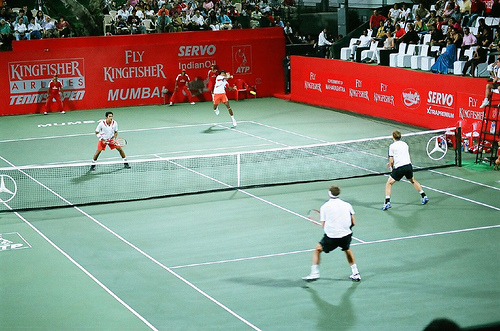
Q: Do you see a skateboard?
A: No, there are no skateboards.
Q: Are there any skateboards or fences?
A: No, there are no skateboards or fences.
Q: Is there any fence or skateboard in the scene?
A: No, there are no skateboards or fences.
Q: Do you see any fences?
A: No, there are no fences.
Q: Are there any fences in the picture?
A: No, there are no fences.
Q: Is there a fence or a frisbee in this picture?
A: No, there are no fences or frisbees.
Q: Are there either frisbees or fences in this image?
A: No, there are no fences or frisbees.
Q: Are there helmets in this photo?
A: No, there are no helmets.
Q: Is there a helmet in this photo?
A: No, there are no helmets.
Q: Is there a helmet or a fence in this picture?
A: No, there are no helmets or fences.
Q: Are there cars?
A: No, there are no cars.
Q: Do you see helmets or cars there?
A: No, there are no cars or helmets.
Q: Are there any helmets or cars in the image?
A: No, there are no cars or helmets.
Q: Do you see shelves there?
A: No, there are no shelves.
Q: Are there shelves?
A: No, there are no shelves.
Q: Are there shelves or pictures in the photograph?
A: No, there are no shelves or pictures.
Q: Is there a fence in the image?
A: No, there are no fences.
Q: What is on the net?
A: The logo is on the net.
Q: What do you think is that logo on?
A: The logo is on the net.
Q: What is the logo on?
A: The logo is on the net.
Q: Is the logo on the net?
A: Yes, the logo is on the net.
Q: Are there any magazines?
A: No, there are no magazines.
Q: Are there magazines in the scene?
A: No, there are no magazines.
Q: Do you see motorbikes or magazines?
A: No, there are no magazines or motorbikes.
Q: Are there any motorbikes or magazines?
A: No, there are no magazines or motorbikes.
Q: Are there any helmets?
A: No, there are no helmets.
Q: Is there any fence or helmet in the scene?
A: No, there are no helmets or fences.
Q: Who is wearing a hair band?
A: The man is wearing a hair band.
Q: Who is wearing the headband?
A: The man is wearing a hair band.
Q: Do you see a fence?
A: No, there are no fences.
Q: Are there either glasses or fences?
A: No, there are no fences or glasses.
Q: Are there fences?
A: No, there are no fences.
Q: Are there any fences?
A: No, there are no fences.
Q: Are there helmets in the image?
A: No, there are no helmets.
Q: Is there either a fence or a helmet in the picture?
A: No, there are no helmets or fences.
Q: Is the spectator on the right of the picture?
A: Yes, the spectator is on the right of the image.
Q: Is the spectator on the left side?
A: No, the spectator is on the right of the image.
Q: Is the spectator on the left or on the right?
A: The spectator is on the right of the image.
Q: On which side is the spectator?
A: The spectator is on the right of the image.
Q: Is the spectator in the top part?
A: Yes, the spectator is in the top of the image.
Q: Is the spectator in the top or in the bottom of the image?
A: The spectator is in the top of the image.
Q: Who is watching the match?
A: The spectator is watching the match.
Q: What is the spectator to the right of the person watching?
A: The spectator is watching the match.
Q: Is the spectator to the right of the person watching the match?
A: Yes, the spectator is watching the match.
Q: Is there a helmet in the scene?
A: No, there are no helmets.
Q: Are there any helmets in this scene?
A: No, there are no helmets.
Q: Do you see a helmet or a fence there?
A: No, there are no helmets or fences.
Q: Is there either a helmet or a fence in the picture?
A: No, there are no helmets or fences.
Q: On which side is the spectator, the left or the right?
A: The spectator is on the right of the image.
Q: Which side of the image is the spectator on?
A: The spectator is on the right of the image.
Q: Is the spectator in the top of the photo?
A: Yes, the spectator is in the top of the image.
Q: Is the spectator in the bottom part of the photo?
A: No, the spectator is in the top of the image.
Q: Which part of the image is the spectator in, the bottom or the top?
A: The spectator is in the top of the image.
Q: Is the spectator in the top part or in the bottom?
A: The spectator is in the top of the image.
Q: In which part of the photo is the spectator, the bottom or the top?
A: The spectator is in the top of the image.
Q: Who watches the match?
A: The spectator watches the match.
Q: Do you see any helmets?
A: No, there are no helmets.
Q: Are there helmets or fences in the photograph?
A: No, there are no helmets or fences.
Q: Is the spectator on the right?
A: Yes, the spectator is on the right of the image.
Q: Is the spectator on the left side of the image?
A: No, the spectator is on the right of the image.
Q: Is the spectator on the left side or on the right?
A: The spectator is on the right of the image.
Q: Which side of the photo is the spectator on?
A: The spectator is on the right of the image.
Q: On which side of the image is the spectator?
A: The spectator is on the right of the image.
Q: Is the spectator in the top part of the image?
A: Yes, the spectator is in the top of the image.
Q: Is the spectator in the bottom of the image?
A: No, the spectator is in the top of the image.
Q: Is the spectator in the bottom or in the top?
A: The spectator is in the top of the image.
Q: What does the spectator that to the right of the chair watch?
A: The spectator watches the match.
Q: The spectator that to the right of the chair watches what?
A: The spectator watches the match.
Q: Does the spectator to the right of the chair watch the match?
A: Yes, the spectator watches the match.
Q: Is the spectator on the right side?
A: Yes, the spectator is on the right of the image.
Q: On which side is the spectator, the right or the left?
A: The spectator is on the right of the image.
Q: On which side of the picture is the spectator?
A: The spectator is on the right of the image.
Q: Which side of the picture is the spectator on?
A: The spectator is on the right of the image.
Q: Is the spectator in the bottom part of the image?
A: No, the spectator is in the top of the image.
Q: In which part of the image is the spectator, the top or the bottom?
A: The spectator is in the top of the image.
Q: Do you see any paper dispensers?
A: No, there are no paper dispensers.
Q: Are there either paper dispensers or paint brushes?
A: No, there are no paper dispensers or paint brushes.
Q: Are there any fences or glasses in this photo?
A: No, there are no fences or glasses.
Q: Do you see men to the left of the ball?
A: Yes, there is a man to the left of the ball.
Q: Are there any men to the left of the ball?
A: Yes, there is a man to the left of the ball.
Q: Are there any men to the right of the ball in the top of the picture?
A: No, the man is to the left of the ball.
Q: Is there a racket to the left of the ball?
A: No, there is a man to the left of the ball.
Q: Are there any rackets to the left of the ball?
A: No, there is a man to the left of the ball.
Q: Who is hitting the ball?
A: The man is hitting the ball.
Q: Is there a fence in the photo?
A: No, there are no fences.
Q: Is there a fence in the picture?
A: No, there are no fences.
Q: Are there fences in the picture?
A: No, there are no fences.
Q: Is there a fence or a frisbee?
A: No, there are no fences or frisbees.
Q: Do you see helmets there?
A: No, there are no helmets.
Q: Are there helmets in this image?
A: No, there are no helmets.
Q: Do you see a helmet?
A: No, there are no helmets.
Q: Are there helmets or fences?
A: No, there are no helmets or fences.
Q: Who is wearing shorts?
A: The man is wearing shorts.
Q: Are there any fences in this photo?
A: No, there are no fences.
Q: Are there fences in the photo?
A: No, there are no fences.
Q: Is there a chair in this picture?
A: Yes, there is a chair.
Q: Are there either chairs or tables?
A: Yes, there is a chair.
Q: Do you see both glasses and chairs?
A: No, there is a chair but no glasses.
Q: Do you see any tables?
A: No, there are no tables.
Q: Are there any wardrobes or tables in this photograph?
A: No, there are no tables or wardrobes.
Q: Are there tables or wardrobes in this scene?
A: No, there are no tables or wardrobes.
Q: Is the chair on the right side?
A: Yes, the chair is on the right of the image.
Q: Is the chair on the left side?
A: No, the chair is on the right of the image.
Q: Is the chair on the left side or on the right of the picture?
A: The chair is on the right of the image.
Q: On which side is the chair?
A: The chair is on the right of the image.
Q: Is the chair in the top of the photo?
A: Yes, the chair is in the top of the image.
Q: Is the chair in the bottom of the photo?
A: No, the chair is in the top of the image.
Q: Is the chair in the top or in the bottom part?
A: The chair is in the top of the image.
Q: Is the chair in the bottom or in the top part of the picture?
A: The chair is in the top of the image.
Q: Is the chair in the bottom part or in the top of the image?
A: The chair is in the top of the image.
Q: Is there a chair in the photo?
A: Yes, there is a chair.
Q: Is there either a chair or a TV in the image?
A: Yes, there is a chair.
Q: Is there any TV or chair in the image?
A: Yes, there is a chair.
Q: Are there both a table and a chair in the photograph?
A: No, there is a chair but no tables.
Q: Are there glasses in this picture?
A: No, there are no glasses.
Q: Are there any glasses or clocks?
A: No, there are no glasses or clocks.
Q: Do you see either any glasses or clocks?
A: No, there are no glasses or clocks.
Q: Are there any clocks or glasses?
A: No, there are no glasses or clocks.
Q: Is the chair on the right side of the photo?
A: Yes, the chair is on the right of the image.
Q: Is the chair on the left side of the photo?
A: No, the chair is on the right of the image.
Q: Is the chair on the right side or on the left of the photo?
A: The chair is on the right of the image.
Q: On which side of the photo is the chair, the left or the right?
A: The chair is on the right of the image.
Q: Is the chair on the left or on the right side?
A: The chair is on the right of the image.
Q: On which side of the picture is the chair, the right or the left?
A: The chair is on the right of the image.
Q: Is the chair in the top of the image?
A: Yes, the chair is in the top of the image.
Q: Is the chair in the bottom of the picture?
A: No, the chair is in the top of the image.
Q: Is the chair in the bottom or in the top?
A: The chair is in the top of the image.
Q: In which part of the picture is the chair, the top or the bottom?
A: The chair is in the top of the image.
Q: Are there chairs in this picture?
A: Yes, there is a chair.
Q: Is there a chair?
A: Yes, there is a chair.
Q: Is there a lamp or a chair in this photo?
A: Yes, there is a chair.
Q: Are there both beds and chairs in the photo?
A: No, there is a chair but no beds.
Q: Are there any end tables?
A: No, there are no end tables.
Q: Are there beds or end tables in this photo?
A: No, there are no end tables or beds.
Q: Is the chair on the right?
A: Yes, the chair is on the right of the image.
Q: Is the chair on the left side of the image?
A: No, the chair is on the right of the image.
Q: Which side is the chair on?
A: The chair is on the right of the image.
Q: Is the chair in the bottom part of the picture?
A: No, the chair is in the top of the image.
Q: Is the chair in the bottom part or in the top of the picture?
A: The chair is in the top of the image.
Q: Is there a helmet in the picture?
A: No, there are no helmets.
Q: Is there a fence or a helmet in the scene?
A: No, there are no helmets or fences.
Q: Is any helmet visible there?
A: No, there are no helmets.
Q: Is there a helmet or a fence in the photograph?
A: No, there are no helmets or fences.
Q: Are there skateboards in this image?
A: No, there are no skateboards.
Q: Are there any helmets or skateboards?
A: No, there are no skateboards or helmets.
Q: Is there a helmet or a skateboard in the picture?
A: No, there are no skateboards or helmets.